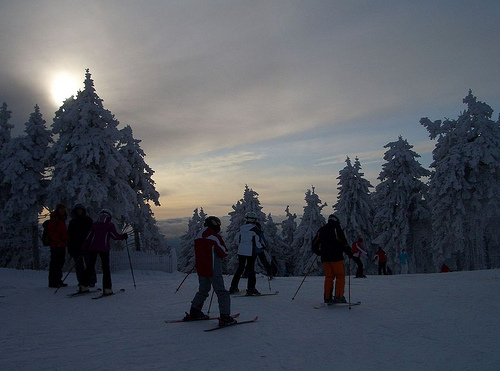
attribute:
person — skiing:
[313, 212, 363, 309]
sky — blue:
[2, 1, 498, 220]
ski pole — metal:
[346, 253, 354, 310]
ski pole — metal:
[290, 255, 321, 302]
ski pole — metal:
[175, 262, 197, 292]